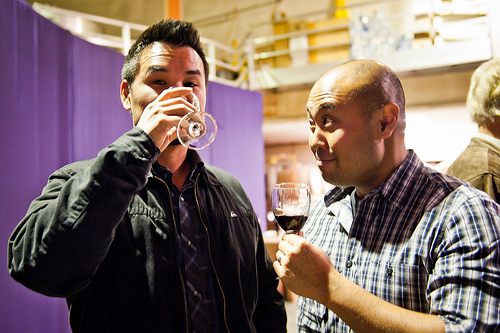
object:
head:
[306, 58, 405, 188]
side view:
[303, 58, 405, 187]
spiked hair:
[119, 16, 211, 85]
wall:
[0, 0, 267, 332]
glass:
[186, 122, 205, 135]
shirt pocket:
[367, 258, 416, 309]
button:
[344, 259, 352, 269]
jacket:
[8, 126, 288, 332]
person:
[445, 56, 499, 204]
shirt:
[297, 147, 499, 333]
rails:
[247, 20, 352, 48]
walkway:
[34, 0, 500, 90]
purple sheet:
[1, 0, 266, 331]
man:
[6, 17, 287, 332]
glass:
[271, 182, 310, 281]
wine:
[275, 214, 307, 231]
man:
[270, 57, 500, 331]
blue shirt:
[153, 157, 221, 332]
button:
[383, 267, 394, 277]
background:
[0, 0, 499, 332]